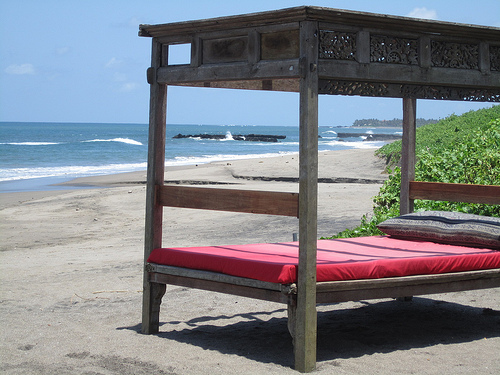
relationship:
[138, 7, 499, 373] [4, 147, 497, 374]
bed on beach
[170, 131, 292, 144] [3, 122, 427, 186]
rocks are in ocean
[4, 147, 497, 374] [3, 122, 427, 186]
beach beside ocean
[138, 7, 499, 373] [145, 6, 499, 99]
bed has canopy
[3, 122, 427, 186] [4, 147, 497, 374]
ocean beside beach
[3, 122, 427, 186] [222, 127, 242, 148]
ocean has waves